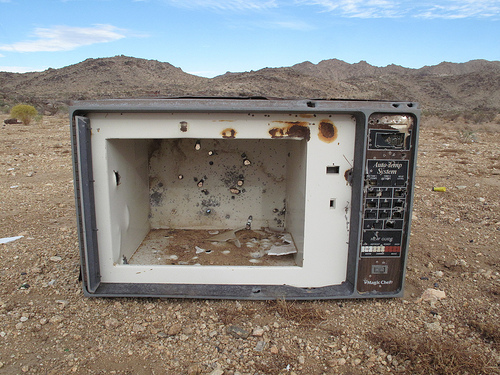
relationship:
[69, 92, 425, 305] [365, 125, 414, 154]
microwave has dial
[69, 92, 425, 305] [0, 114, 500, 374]
microwave in dirt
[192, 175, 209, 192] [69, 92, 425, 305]
bullet hole in a microwave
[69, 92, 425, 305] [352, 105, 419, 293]
microwave has control panel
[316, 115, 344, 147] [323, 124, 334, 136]
area surrounding hole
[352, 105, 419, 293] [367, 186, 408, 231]
control panel has holes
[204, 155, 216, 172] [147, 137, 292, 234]
hole through back wall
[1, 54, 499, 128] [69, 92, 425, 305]
hill behind microwave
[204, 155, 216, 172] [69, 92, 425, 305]
hole in back of microwave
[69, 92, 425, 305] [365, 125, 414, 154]
microwave on dial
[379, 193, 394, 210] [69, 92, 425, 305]
button on microwave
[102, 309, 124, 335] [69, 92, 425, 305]
rock under microwave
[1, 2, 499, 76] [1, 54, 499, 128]
sky above hill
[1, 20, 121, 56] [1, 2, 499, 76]
cloud in sky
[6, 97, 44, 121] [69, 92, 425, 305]
bush behind microwave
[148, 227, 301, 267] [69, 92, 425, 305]
dirt in bottom of microwave